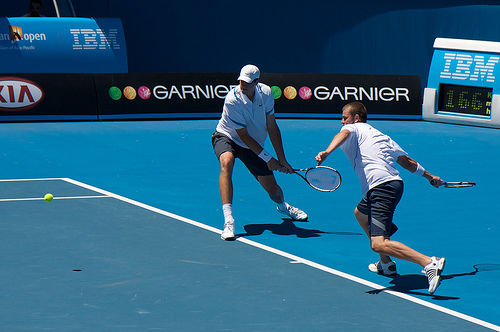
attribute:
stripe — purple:
[369, 214, 392, 232]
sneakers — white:
[422, 255, 445, 295]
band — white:
[416, 161, 425, 179]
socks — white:
[222, 199, 234, 219]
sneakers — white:
[222, 223, 238, 243]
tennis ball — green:
[41, 190, 55, 200]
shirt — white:
[337, 123, 404, 190]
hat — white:
[234, 63, 259, 83]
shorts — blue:
[352, 179, 401, 237]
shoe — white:
[419, 255, 444, 296]